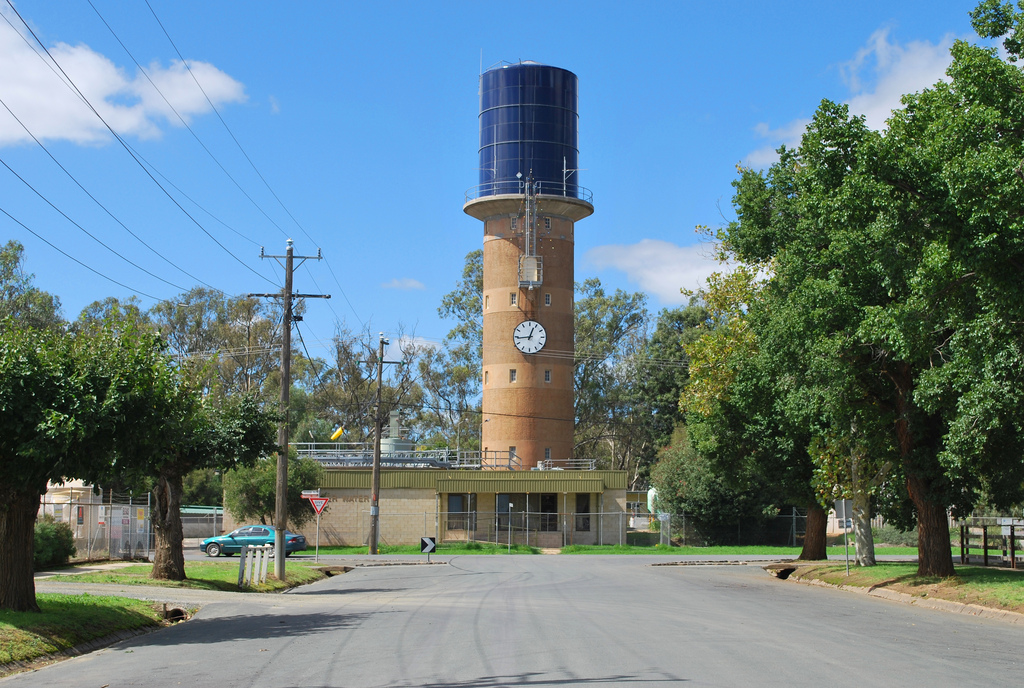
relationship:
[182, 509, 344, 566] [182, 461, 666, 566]
car outside building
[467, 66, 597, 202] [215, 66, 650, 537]
tower on top of building